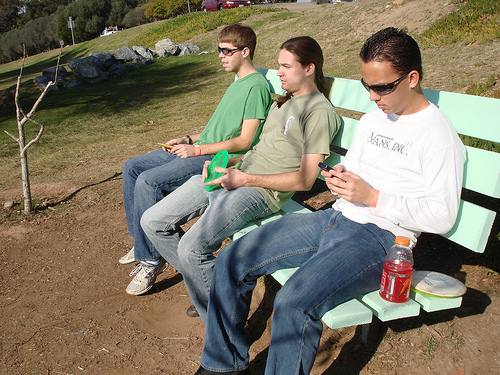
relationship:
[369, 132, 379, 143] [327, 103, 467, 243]
letter in shirt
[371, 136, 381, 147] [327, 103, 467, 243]
letter in shirt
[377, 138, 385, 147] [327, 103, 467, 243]
letter in shirt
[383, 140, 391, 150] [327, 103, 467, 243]
letter in shirt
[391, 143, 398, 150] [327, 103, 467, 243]
letter in shirt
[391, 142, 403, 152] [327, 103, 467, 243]
letter in shirt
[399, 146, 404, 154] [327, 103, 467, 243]
letter in shirt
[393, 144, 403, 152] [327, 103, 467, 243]
black letter in shirt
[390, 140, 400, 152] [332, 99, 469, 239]
black letter in shirt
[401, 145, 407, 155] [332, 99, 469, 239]
letter on shirt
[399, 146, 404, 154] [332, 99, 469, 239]
letter on shirt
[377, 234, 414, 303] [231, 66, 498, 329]
bottle on bench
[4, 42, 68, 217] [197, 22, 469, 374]
tree near man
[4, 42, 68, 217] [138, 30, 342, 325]
tree near man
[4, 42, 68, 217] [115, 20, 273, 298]
tree near man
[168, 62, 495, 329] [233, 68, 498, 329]
bench has bench